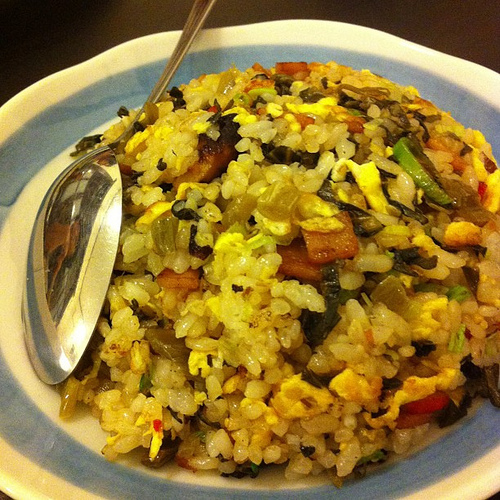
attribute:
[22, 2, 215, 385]
spoon — silver., shiny.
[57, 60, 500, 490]
rice — white., ingredient.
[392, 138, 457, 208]
peppers — showing.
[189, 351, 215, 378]
tiny — yellow